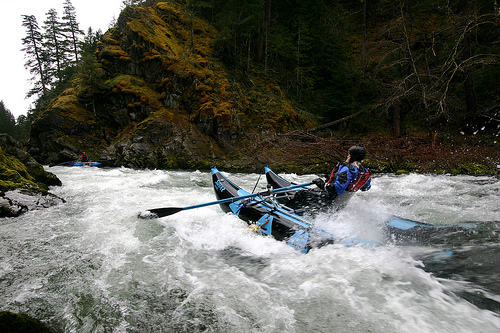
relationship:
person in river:
[296, 139, 374, 225] [73, 171, 486, 324]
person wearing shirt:
[296, 139, 374, 225] [338, 166, 361, 188]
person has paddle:
[296, 139, 374, 225] [138, 202, 196, 224]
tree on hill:
[17, 0, 90, 85] [47, 89, 113, 126]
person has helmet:
[296, 139, 374, 225] [350, 149, 362, 158]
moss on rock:
[166, 156, 176, 161] [120, 121, 176, 164]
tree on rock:
[17, 0, 90, 85] [120, 121, 176, 164]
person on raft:
[296, 139, 374, 225] [221, 184, 315, 240]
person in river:
[77, 150, 91, 162] [73, 171, 486, 324]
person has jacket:
[296, 139, 374, 225] [340, 162, 369, 193]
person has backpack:
[296, 139, 374, 225] [358, 173, 367, 191]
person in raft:
[77, 150, 91, 162] [74, 164, 97, 167]